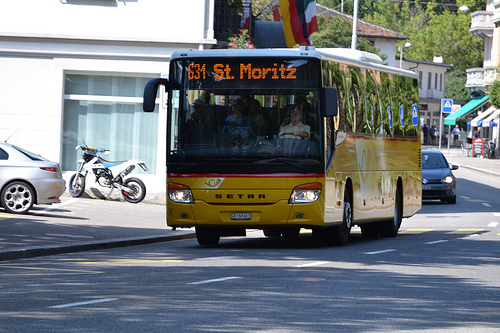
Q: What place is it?
A: It is a road.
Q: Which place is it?
A: It is a road.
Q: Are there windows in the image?
A: Yes, there is a window.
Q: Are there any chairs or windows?
A: Yes, there is a window.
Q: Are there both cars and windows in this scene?
A: Yes, there are both a window and a car.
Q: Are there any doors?
A: No, there are no doors.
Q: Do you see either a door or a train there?
A: No, there are no doors or trains.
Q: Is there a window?
A: Yes, there is a window.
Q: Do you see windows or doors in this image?
A: Yes, there is a window.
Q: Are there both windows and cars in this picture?
A: Yes, there are both a window and a car.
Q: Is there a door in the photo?
A: No, there are no doors.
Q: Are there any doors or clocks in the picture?
A: No, there are no doors or clocks.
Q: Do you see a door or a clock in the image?
A: No, there are no doors or clocks.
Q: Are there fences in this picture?
A: No, there are no fences.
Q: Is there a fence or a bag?
A: No, there are no fences or bags.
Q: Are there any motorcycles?
A: Yes, there is a motorcycle.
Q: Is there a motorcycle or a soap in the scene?
A: Yes, there is a motorcycle.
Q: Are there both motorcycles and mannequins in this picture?
A: No, there is a motorcycle but no mannequins.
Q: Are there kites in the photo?
A: No, there are no kites.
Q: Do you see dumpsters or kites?
A: No, there are no kites or dumpsters.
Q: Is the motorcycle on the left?
A: Yes, the motorcycle is on the left of the image.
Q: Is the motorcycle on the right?
A: No, the motorcycle is on the left of the image.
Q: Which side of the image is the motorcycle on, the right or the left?
A: The motorcycle is on the left of the image.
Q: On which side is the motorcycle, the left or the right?
A: The motorcycle is on the left of the image.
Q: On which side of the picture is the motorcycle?
A: The motorcycle is on the left of the image.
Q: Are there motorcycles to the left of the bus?
A: Yes, there is a motorcycle to the left of the bus.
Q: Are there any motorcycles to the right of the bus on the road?
A: No, the motorcycle is to the left of the bus.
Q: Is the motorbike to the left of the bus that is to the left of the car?
A: Yes, the motorbike is to the left of the bus.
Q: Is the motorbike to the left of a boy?
A: No, the motorbike is to the left of the bus.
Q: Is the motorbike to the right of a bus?
A: No, the motorbike is to the left of a bus.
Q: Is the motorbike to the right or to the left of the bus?
A: The motorbike is to the left of the bus.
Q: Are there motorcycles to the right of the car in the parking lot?
A: Yes, there is a motorcycle to the right of the car.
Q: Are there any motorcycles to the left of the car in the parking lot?
A: No, the motorcycle is to the right of the car.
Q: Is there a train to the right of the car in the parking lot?
A: No, there is a motorcycle to the right of the car.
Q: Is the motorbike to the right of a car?
A: Yes, the motorbike is to the right of a car.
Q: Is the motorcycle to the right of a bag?
A: No, the motorcycle is to the right of a car.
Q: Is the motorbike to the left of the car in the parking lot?
A: No, the motorbike is to the right of the car.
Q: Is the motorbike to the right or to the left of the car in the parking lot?
A: The motorbike is to the right of the car.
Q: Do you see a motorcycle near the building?
A: Yes, there is a motorcycle near the building.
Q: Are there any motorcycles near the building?
A: Yes, there is a motorcycle near the building.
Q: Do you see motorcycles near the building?
A: Yes, there is a motorcycle near the building.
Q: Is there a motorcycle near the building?
A: Yes, there is a motorcycle near the building.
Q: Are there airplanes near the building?
A: No, there is a motorcycle near the building.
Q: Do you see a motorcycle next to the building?
A: Yes, there is a motorcycle next to the building.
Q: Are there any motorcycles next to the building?
A: Yes, there is a motorcycle next to the building.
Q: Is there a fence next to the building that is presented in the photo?
A: No, there is a motorcycle next to the building.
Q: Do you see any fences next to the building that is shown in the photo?
A: No, there is a motorcycle next to the building.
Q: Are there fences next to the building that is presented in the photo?
A: No, there is a motorcycle next to the building.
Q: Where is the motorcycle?
A: The motorcycle is on the sidewalk.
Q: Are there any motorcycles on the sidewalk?
A: Yes, there is a motorcycle on the sidewalk.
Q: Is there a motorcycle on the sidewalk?
A: Yes, there is a motorcycle on the sidewalk.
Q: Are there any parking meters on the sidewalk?
A: No, there is a motorcycle on the sidewalk.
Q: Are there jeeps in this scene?
A: No, there are no jeeps.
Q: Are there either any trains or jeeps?
A: No, there are no jeeps or trains.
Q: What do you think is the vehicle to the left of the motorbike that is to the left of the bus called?
A: The vehicle is a car.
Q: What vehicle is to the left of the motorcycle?
A: The vehicle is a car.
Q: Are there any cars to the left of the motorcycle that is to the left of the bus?
A: Yes, there is a car to the left of the motorbike.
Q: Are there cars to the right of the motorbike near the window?
A: No, the car is to the left of the motorcycle.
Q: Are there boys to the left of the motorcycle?
A: No, there is a car to the left of the motorcycle.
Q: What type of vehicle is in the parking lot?
A: The vehicle is a car.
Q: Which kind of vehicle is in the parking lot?
A: The vehicle is a car.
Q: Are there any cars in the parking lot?
A: Yes, there is a car in the parking lot.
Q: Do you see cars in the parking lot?
A: Yes, there is a car in the parking lot.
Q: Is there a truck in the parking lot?
A: No, there is a car in the parking lot.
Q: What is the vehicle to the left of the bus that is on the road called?
A: The vehicle is a car.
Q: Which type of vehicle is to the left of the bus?
A: The vehicle is a car.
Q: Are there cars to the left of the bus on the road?
A: Yes, there is a car to the left of the bus.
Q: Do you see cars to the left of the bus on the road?
A: Yes, there is a car to the left of the bus.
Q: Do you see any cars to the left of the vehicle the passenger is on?
A: Yes, there is a car to the left of the bus.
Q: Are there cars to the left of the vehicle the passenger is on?
A: Yes, there is a car to the left of the bus.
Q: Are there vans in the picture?
A: No, there are no vans.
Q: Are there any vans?
A: No, there are no vans.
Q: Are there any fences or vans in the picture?
A: No, there are no vans or fences.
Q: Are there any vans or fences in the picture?
A: No, there are no vans or fences.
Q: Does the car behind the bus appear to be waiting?
A: No, the car is driving.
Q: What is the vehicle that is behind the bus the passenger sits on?
A: The vehicle is a car.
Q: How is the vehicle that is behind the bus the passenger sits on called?
A: The vehicle is a car.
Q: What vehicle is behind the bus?
A: The vehicle is a car.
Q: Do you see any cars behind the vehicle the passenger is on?
A: Yes, there is a car behind the bus.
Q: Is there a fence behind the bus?
A: No, there is a car behind the bus.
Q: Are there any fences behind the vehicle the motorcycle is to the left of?
A: No, there is a car behind the bus.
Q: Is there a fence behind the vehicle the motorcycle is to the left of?
A: No, there is a car behind the bus.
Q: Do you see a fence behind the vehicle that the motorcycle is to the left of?
A: No, there is a car behind the bus.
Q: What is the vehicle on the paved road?
A: The vehicle is a car.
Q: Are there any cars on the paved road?
A: Yes, there is a car on the road.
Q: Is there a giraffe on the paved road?
A: No, there is a car on the road.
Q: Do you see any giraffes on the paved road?
A: No, there is a car on the road.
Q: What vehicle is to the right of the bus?
A: The vehicle is a car.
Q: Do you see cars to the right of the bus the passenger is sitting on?
A: Yes, there is a car to the right of the bus.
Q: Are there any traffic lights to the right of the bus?
A: No, there is a car to the right of the bus.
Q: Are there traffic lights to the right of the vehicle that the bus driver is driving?
A: No, there is a car to the right of the bus.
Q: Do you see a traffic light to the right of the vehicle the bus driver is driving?
A: No, there is a car to the right of the bus.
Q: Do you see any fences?
A: No, there are no fences.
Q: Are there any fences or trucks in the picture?
A: No, there are no fences or trucks.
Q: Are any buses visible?
A: Yes, there is a bus.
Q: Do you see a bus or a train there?
A: Yes, there is a bus.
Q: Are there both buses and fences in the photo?
A: No, there is a bus but no fences.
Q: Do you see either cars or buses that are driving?
A: Yes, the bus is driving.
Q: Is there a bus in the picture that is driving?
A: Yes, there is a bus that is driving.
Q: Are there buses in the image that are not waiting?
A: Yes, there is a bus that is driving.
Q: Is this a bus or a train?
A: This is a bus.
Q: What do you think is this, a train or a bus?
A: This is a bus.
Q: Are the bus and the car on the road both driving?
A: Yes, both the bus and the car are driving.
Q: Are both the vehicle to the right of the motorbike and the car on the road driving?
A: Yes, both the bus and the car are driving.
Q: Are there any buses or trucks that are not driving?
A: No, there is a bus but it is driving.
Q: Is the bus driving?
A: Yes, the bus is driving.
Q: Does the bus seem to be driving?
A: Yes, the bus is driving.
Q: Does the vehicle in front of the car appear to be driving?
A: Yes, the bus is driving.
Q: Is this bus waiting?
A: No, the bus is driving.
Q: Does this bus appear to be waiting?
A: No, the bus is driving.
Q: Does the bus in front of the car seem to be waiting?
A: No, the bus is driving.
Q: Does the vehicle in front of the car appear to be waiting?
A: No, the bus is driving.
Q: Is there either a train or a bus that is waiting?
A: No, there is a bus but it is driving.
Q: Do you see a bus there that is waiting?
A: No, there is a bus but it is driving.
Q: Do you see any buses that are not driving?
A: No, there is a bus but it is driving.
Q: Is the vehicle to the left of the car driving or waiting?
A: The bus is driving.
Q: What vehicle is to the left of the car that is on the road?
A: The vehicle is a bus.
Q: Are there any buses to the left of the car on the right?
A: Yes, there is a bus to the left of the car.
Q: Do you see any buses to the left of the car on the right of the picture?
A: Yes, there is a bus to the left of the car.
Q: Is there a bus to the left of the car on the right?
A: Yes, there is a bus to the left of the car.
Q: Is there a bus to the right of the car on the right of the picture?
A: No, the bus is to the left of the car.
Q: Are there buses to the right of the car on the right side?
A: No, the bus is to the left of the car.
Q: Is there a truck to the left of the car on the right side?
A: No, there is a bus to the left of the car.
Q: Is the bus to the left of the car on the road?
A: Yes, the bus is to the left of the car.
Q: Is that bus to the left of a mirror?
A: No, the bus is to the left of the car.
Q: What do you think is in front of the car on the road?
A: The bus is in front of the car.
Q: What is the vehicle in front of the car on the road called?
A: The vehicle is a bus.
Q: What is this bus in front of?
A: The bus is in front of the car.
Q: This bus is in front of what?
A: The bus is in front of the car.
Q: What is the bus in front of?
A: The bus is in front of the car.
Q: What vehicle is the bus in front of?
A: The bus is in front of the car.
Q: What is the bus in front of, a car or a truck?
A: The bus is in front of a car.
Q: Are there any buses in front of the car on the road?
A: Yes, there is a bus in front of the car.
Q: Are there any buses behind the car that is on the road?
A: No, the bus is in front of the car.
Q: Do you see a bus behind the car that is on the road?
A: No, the bus is in front of the car.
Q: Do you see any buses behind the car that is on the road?
A: No, the bus is in front of the car.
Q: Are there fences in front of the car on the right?
A: No, there is a bus in front of the car.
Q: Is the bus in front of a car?
A: Yes, the bus is in front of a car.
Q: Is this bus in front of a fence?
A: No, the bus is in front of a car.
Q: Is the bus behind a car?
A: No, the bus is in front of a car.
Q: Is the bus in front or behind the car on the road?
A: The bus is in front of the car.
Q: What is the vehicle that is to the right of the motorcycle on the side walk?
A: The vehicle is a bus.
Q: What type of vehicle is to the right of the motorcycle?
A: The vehicle is a bus.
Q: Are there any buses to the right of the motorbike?
A: Yes, there is a bus to the right of the motorbike.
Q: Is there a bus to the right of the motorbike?
A: Yes, there is a bus to the right of the motorbike.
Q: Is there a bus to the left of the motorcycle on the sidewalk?
A: No, the bus is to the right of the motorcycle.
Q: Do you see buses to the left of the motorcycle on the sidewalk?
A: No, the bus is to the right of the motorcycle.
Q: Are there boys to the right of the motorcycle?
A: No, there is a bus to the right of the motorcycle.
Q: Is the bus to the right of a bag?
A: No, the bus is to the right of a motorcycle.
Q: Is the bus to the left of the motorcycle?
A: No, the bus is to the right of the motorcycle.